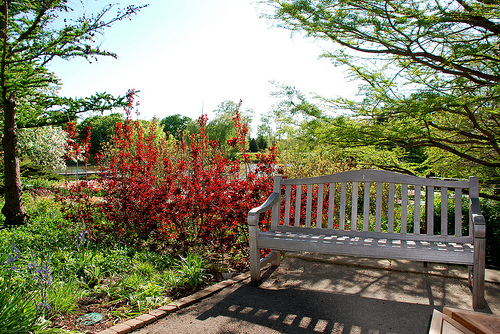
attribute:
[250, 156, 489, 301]
bench — white, park, light, wooden, grey, empty, shadow, curved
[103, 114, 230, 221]
bush — red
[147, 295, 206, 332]
bricks — paver, row, edging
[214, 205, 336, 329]
patio — paved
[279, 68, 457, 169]
tree — green, covered, variety, long, leafy, background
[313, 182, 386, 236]
slat — wooden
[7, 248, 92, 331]
flowers — blue, red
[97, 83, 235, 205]
plant — large, surrounded, small, purple, red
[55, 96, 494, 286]
setting — park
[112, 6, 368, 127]
sky — blue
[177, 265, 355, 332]
ground — paved